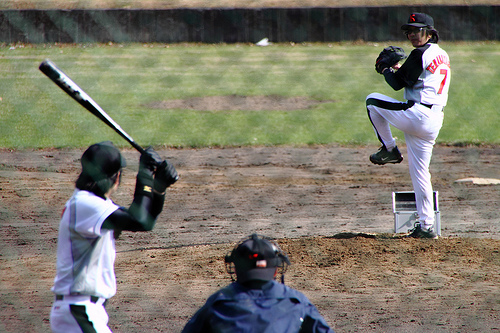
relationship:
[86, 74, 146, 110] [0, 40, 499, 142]
patch of grass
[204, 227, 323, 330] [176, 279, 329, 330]
person wearing shirt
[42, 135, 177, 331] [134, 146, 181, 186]
person wearing glove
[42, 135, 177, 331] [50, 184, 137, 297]
person wearing shirt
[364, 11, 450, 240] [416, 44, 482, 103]
person wearing shirt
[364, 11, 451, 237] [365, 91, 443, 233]
person wearing pants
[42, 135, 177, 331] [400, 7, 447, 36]
person wearing hat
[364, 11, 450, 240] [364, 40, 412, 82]
person wearing glove